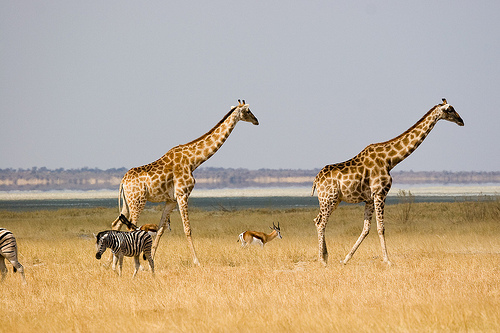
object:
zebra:
[92, 230, 155, 279]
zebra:
[0, 227, 23, 276]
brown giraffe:
[109, 98, 260, 268]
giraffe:
[311, 97, 464, 267]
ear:
[242, 99, 246, 104]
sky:
[0, 0, 500, 173]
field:
[81, 197, 381, 309]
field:
[1, 182, 385, 319]